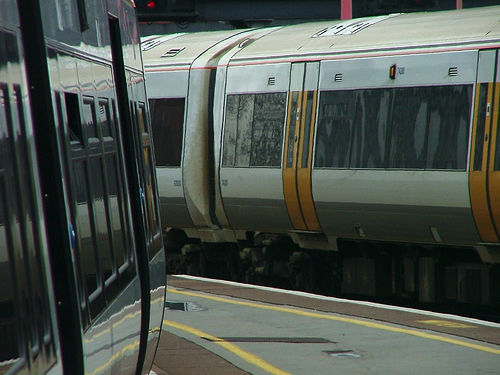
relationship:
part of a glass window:
[386, 153, 415, 187] [355, 85, 412, 147]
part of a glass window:
[414, 141, 430, 164] [373, 99, 455, 220]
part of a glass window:
[346, 157, 366, 168] [314, 50, 377, 170]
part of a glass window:
[170, 144, 179, 161] [226, 99, 284, 166]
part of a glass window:
[260, 155, 281, 172] [219, 63, 286, 171]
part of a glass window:
[154, 155, 180, 177] [156, 105, 184, 224]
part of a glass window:
[128, 220, 145, 239] [104, 69, 169, 206]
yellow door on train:
[291, 78, 311, 156] [225, 99, 395, 225]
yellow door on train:
[291, 78, 311, 156] [292, 89, 322, 189]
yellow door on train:
[457, 50, 491, 218] [394, 172, 451, 256]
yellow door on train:
[467, 50, 499, 218] [381, 118, 411, 171]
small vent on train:
[263, 75, 277, 91] [220, 114, 270, 217]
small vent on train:
[341, 99, 354, 104] [322, 147, 353, 187]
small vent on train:
[448, 67, 458, 78] [364, 174, 434, 243]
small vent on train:
[166, 100, 178, 115] [152, 169, 196, 225]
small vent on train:
[164, 165, 183, 194] [227, 179, 241, 223]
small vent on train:
[215, 174, 234, 191] [317, 170, 338, 197]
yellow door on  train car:
[291, 78, 311, 156] [242, 147, 256, 201]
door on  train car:
[279, 59, 319, 235] [240, 164, 274, 213]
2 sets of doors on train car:
[242, 99, 486, 244] [343, 201, 374, 232]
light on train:
[384, 60, 399, 86] [141, 3, 482, 310]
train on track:
[141, 3, 482, 310] [163, 259, 477, 329]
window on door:
[285, 88, 311, 167] [279, 59, 319, 235]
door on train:
[279, 59, 319, 235] [141, 3, 482, 310]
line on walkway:
[165, 283, 484, 353] [153, 269, 484, 369]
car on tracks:
[209, 1, 477, 312] [166, 246, 479, 336]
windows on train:
[42, 30, 142, 335] [2, 1, 168, 367]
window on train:
[220, 87, 284, 169] [141, 3, 482, 310]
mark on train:
[309, 13, 398, 39] [141, 3, 482, 310]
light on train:
[388, 61, 396, 79] [141, 3, 482, 310]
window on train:
[62, 88, 88, 148] [2, 1, 168, 367]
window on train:
[77, 96, 99, 141] [2, 1, 168, 367]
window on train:
[95, 95, 114, 138] [2, 1, 168, 367]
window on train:
[134, 100, 149, 140] [2, 1, 168, 367]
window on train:
[313, 87, 356, 174] [141, 3, 482, 310]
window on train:
[351, 87, 388, 167] [141, 3, 482, 310]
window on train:
[383, 80, 429, 175] [141, 3, 482, 310]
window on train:
[423, 82, 471, 170] [141, 3, 482, 310]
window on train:
[251, 90, 284, 169] [141, 3, 482, 310]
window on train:
[221, 90, 250, 164] [141, 3, 482, 310]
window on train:
[222, 95, 286, 169] [159, 5, 479, 285]